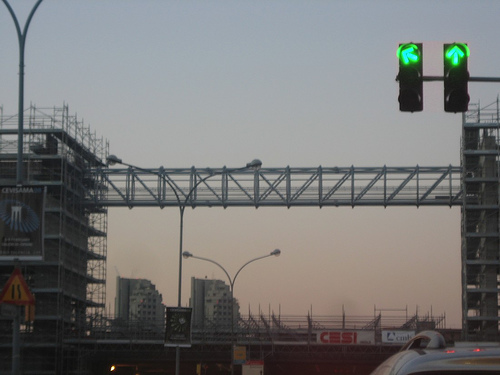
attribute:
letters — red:
[324, 333, 359, 344]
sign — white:
[313, 328, 369, 354]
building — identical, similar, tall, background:
[187, 275, 257, 333]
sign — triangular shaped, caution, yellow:
[3, 269, 42, 329]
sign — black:
[166, 297, 201, 348]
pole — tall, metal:
[169, 272, 198, 297]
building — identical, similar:
[110, 281, 172, 334]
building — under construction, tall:
[10, 114, 110, 372]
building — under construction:
[451, 114, 497, 258]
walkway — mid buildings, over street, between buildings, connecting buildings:
[96, 144, 462, 226]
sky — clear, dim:
[268, 19, 324, 52]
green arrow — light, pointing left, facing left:
[399, 45, 416, 63]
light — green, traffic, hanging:
[398, 41, 422, 118]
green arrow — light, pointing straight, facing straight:
[446, 43, 466, 67]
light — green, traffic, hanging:
[443, 42, 467, 119]